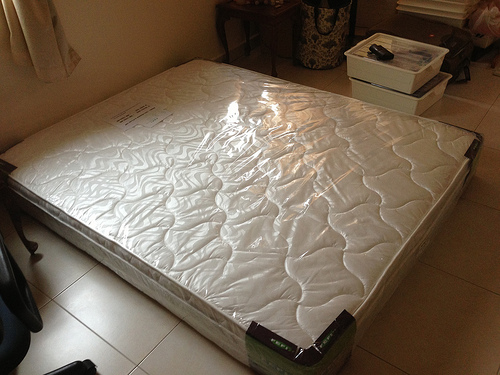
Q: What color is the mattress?
A: White.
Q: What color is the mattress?
A: White.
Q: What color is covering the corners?
A: Black.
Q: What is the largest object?
A: Mattress.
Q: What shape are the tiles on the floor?
A: Square.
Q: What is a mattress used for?
A: Sleeping.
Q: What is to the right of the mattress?
A: Two bins.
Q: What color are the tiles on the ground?
A: White.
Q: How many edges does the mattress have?
A: Four.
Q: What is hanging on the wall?
A: Towel.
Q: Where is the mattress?
A: Floor.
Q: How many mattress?
A: 1.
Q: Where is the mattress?
A: Floor.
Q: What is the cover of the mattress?
A: Plastic.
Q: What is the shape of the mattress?
A: Rectangle.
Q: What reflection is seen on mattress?
A: SunLight.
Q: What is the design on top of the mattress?
A: Curve.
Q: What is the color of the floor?
A: White.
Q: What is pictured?
A: Mattress.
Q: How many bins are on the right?
A: 2.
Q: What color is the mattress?
A: White.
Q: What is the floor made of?
A: Tile.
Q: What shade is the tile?
A: White.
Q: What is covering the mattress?
A: Plastic.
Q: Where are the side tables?
A: Beside the mattress.